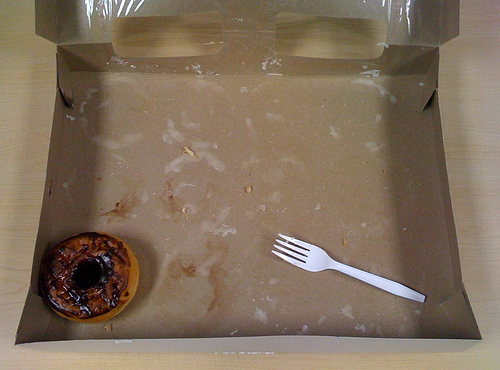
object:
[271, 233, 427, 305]
fork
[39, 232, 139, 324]
doughnut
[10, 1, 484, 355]
box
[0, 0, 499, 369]
table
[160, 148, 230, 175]
sugar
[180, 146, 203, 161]
crumbs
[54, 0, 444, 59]
plastic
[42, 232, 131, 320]
chocolate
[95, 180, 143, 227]
smear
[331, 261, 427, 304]
fork handle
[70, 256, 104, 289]
center